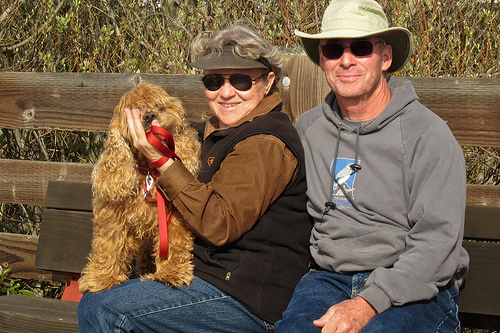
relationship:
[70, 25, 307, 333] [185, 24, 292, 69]
woman has hair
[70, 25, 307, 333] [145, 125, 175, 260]
woman holding red leash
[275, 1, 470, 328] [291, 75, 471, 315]
man wearing gray shirt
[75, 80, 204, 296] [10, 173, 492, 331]
dog on bench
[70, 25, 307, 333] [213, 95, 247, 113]
woman with smile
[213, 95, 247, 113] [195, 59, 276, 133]
smile on face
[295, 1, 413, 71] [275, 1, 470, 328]
hat on man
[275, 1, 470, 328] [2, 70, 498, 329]
man sitting on bench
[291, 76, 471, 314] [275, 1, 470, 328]
gray shirt on man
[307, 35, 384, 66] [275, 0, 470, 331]
sunglasses on man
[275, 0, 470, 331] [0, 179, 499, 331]
man sitting on bench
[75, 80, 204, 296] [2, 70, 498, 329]
dog on bench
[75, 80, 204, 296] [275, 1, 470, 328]
dog with man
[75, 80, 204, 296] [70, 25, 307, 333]
dog with woman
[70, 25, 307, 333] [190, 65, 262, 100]
woman wearing sunglasses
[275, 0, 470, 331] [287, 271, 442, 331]
man wearing blue jeans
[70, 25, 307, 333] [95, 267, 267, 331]
woman wearing jeans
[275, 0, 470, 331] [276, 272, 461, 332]
man wearing blue jeans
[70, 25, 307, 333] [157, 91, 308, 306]
woman wearing vest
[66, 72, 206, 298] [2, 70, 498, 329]
dog sitting on bench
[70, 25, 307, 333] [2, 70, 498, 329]
woman sitting on bench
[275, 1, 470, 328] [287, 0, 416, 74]
man wearing hat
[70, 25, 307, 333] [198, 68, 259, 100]
woman wears sunglasses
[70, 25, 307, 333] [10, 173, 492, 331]
woman on bench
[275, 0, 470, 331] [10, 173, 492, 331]
man on bench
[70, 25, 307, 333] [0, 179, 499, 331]
woman sitting on bench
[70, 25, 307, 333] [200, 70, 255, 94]
woman wearing sunglasses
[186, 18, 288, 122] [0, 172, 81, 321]
woman on bench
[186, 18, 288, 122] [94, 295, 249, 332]
woman wears jeans